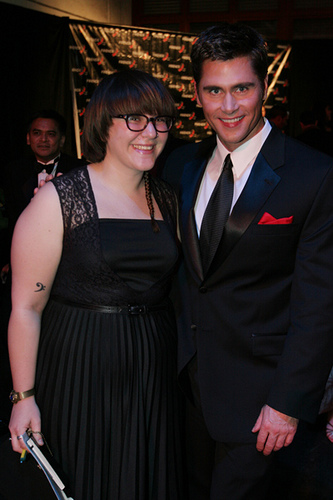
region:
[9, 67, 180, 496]
woman wearing long black dress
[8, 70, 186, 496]
woman with small tattoo on right arm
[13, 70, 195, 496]
woman with short, dark hair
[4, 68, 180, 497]
woman wearing dark framed glasses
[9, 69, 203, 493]
woman holding notebook in hand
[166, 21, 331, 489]
man wearing a black suit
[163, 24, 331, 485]
man wearing a black tie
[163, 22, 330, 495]
man wearing red handkerchief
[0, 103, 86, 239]
man wearing a black suit, standing behind woman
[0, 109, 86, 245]
man wearing black bowtie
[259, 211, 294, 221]
red pocket square in suit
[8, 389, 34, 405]
gold bracelet on girl's wrist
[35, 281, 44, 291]
small black symbol tattooed on arm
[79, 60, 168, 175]
girl with short hair and glasses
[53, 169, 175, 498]
black formal dress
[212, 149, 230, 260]
black tie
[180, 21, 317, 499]
man in black tuxedo with white shirt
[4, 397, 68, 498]
hand holding notebooks and pen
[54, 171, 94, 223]
black lace shoulder strap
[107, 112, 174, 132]
black and brown eyeglasses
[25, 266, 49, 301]
Tattoo on a woman's arm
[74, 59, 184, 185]
A woman with dark brown hair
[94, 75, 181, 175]
A woman wearing glasses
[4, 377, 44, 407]
A woman wearing a wrist watch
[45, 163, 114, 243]
Black lace on a woman's dress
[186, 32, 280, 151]
A man with dark brown hair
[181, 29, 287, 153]
A smiling man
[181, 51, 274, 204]
A man wearing a white dress shirt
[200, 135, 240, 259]
A man wearing a black tie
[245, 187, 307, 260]
A red pocket square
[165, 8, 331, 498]
The man is smiling.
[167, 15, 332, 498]
The man is wearing a suit.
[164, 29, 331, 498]
The man's suit is black.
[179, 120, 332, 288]
A red hankie in suit pocket.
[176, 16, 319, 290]
The man is wearing a black tie.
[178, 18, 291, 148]
The man has red lips.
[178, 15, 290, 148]
The man's hair is neatly groomed.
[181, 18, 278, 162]
The man has short hair.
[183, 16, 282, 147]
The man's hair is dark.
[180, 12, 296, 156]
The man's hair is neat.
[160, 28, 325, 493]
a young man in a suit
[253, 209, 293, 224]
a red pocket handkerchief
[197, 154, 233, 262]
a black neck tie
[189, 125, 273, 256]
a white dress shirt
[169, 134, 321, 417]
a black dress coat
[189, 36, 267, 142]
a man's face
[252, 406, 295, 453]
a man's left hand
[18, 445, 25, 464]
a ball point pen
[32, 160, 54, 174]
a black bow tie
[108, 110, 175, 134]
a pair of eyeglasses